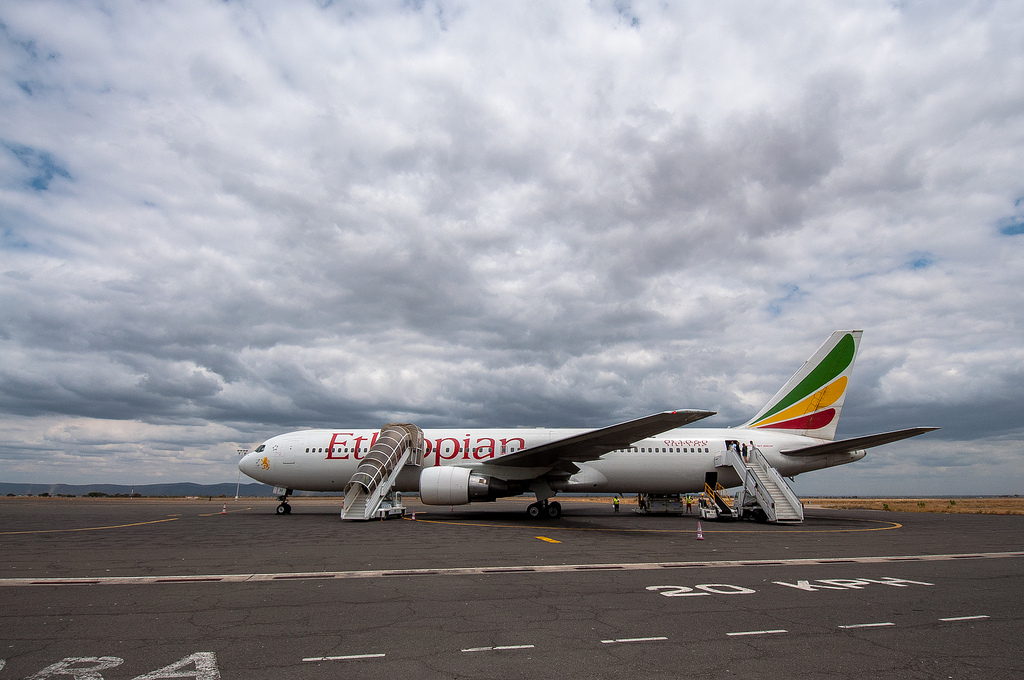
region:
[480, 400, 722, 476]
This is the wing of a plane.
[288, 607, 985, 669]
one way dashed lane markings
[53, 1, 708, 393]
a cloudy sky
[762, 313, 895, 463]
tail of jet aircraft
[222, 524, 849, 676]
tarmac of airport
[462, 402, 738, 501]
left wing of jet aircraft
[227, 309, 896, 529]
a large jet aircraft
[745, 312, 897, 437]
rainbow covered tail of aircraft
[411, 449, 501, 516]
left engine of jet aircraft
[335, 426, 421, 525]
mobile stairway to airplane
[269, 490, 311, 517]
front wheel to airplane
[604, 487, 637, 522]
a person stands near airplane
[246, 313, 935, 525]
a large jet aircraft is parked on the tarmac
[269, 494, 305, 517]
front wheels of the airplane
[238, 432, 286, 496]
cockpit of the airplane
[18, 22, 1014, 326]
clouds in the sky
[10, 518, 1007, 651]
tarmac of the airport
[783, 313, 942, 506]
tail of the airplane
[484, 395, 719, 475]
left wing of the airplane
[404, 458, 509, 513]
left engine of the airplane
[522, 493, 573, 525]
rear landing gear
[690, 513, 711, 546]
pink and white safety cone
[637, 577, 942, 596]
Words written on a runway.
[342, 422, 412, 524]
A covered stairway leading into a plane.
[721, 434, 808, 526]
The back stairway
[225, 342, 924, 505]
A white airplane parked on the tarmac.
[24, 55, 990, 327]
White clouds covering the sky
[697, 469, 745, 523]
A ramp for loading luggage.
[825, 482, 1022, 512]
barren brown land.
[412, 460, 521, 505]
An airplane engine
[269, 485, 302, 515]
Front landing wheels on an airplane.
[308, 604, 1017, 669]
Lane markings on a tarmac.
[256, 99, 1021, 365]
The sky shows heavy cloud banks.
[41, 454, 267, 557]
Shading in distance suggests hills.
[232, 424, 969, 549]
Predominantly, white jet liner.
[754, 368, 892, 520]
Red, yellow and green tail with feather-like design.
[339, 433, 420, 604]
White vehicle beneath stairs with dome-like, roof covering.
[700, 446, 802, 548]
Second vehicle next to stairs without overhead covering.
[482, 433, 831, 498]
Left wing and passenger windows visible.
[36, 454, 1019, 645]
Grey runway with yellow and white markings, including, "20 KPM," and "BA."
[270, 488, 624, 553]
Two sets of plane wheels visible.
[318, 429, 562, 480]
Red lettering, showing airline, partially covered, although, "Eu..pian" is visible.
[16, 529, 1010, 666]
Airport tarmac with markings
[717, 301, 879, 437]
Green, yellow and red logo on tail fin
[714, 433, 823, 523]
Passenger gangway attached to plane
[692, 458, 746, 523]
Baggage loading ramp attached to plane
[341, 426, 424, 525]
Covered passenger ramp attached to plane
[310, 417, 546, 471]
Logo identifying plane's nation of origin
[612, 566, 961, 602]
Speed limit painted on tarmac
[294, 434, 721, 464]
Passenger jet windows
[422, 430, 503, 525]
Engine on passenger plane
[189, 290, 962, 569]
Ethiopian passenger plane parked on tarmac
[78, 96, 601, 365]
Blue clouds.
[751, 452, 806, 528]
Aircraft Stairs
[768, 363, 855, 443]
Airplane tail.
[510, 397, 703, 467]
Airplane wing of airplane sitting on tarmac.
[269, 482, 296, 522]
Airplane landing gear.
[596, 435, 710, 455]
Airplane windows located on right side.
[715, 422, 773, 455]
People boarding airplane.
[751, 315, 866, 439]
Green, yellow, red and white airplane tail.